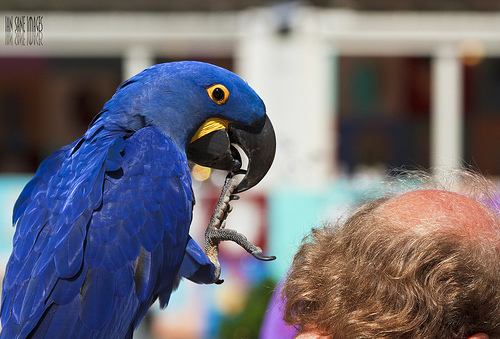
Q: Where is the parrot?
A: By a man's head.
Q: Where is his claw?
A: In his mouth.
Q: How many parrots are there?
A: One.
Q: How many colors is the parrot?
A: Three.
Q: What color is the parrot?
A: Blue.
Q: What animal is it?
A: Parrot.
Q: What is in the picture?
A: Parrot and a man.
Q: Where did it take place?
A: At the zoo.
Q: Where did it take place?
A: At the zoo.